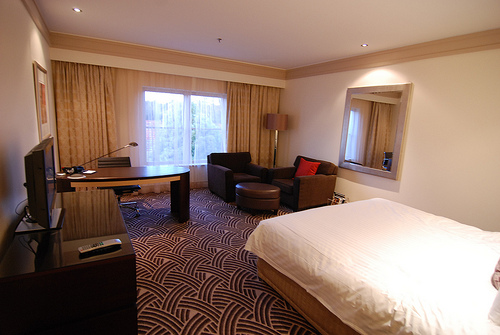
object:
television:
[21, 136, 57, 232]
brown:
[55, 165, 191, 223]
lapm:
[264, 114, 288, 169]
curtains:
[50, 60, 280, 196]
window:
[136, 86, 226, 166]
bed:
[244, 197, 500, 335]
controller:
[77, 238, 124, 256]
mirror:
[337, 82, 420, 180]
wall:
[275, 46, 500, 234]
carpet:
[122, 186, 321, 335]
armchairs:
[208, 151, 270, 203]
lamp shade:
[266, 114, 289, 130]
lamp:
[78, 141, 138, 167]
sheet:
[245, 197, 497, 331]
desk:
[2, 184, 137, 335]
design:
[161, 228, 230, 300]